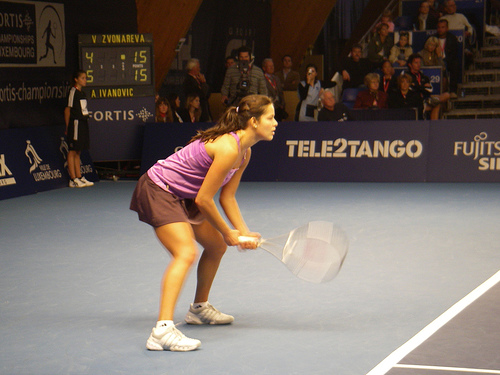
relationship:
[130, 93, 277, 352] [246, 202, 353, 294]
girl holding racket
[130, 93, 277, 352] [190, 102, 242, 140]
girl has pony tail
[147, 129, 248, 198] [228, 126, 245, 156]
pink shirt has strap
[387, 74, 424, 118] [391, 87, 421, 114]
person wearing shirt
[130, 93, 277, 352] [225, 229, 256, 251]
girl has hand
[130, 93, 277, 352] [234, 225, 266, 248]
girl has hand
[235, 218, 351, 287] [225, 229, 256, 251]
racket in hand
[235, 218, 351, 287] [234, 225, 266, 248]
racket in hand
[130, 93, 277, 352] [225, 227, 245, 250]
girl has hand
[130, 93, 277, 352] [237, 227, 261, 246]
girl has hand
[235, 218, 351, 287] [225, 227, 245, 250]
racket in hand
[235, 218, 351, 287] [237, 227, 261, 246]
racket in hand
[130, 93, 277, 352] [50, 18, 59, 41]
girl holding racket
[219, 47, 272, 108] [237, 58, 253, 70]
cameraman with camera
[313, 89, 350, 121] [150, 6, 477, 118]
person in crowd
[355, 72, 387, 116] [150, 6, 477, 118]
person in crowd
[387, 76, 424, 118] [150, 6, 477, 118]
person in crowd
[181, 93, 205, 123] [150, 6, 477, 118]
person in crowd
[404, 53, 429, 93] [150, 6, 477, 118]
person in crowd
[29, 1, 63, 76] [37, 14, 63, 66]
advertisement of player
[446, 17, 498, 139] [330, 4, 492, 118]
stairs in stands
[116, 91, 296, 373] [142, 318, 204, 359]
girl wears shoe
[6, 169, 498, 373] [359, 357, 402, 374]
court has corner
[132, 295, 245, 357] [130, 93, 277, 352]
shoes on girl